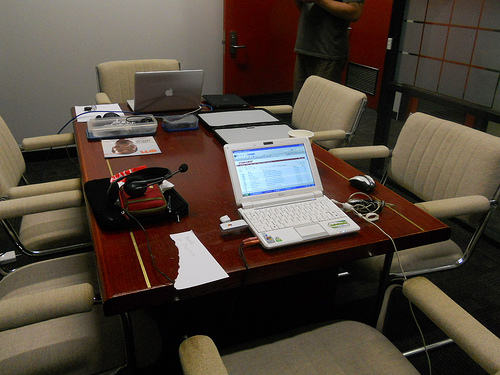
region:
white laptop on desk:
[217, 140, 364, 252]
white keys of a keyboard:
[241, 196, 349, 231]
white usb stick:
[220, 216, 252, 231]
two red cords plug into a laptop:
[241, 234, 266, 245]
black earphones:
[101, 163, 191, 198]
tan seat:
[258, 74, 367, 143]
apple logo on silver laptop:
[159, 84, 179, 101]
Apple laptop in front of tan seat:
[91, 56, 204, 118]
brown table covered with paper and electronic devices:
[73, 71, 450, 309]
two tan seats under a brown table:
[254, 74, 499, 219]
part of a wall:
[147, 2, 179, 27]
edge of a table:
[219, 247, 261, 283]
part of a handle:
[44, 285, 98, 331]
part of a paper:
[174, 243, 199, 280]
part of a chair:
[321, 328, 350, 353]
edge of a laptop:
[254, 224, 306, 256]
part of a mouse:
[353, 172, 382, 198]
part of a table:
[246, 278, 331, 319]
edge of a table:
[109, 295, 130, 309]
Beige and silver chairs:
[6, 50, 496, 368]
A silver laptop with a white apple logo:
[121, 57, 213, 117]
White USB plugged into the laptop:
[215, 209, 251, 236]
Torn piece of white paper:
[149, 227, 239, 311]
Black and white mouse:
[341, 165, 391, 212]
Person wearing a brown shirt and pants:
[291, 5, 380, 125]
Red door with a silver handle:
[220, 5, 317, 115]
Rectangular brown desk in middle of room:
[56, 95, 451, 325]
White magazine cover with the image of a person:
[96, 127, 176, 172]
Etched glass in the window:
[401, 8, 497, 129]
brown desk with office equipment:
[48, 63, 378, 360]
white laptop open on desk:
[213, 115, 362, 251]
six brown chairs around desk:
[16, 48, 437, 360]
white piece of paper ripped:
[162, 233, 249, 325]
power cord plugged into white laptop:
[330, 187, 452, 373]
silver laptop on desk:
[116, 48, 236, 120]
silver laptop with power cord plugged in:
[24, 69, 221, 116]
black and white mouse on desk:
[328, 156, 407, 226]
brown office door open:
[192, 1, 499, 136]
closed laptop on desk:
[201, 96, 296, 160]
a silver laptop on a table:
[127, 63, 210, 117]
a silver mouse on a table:
[348, 168, 373, 193]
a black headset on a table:
[102, 150, 197, 202]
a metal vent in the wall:
[335, 57, 380, 97]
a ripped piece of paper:
[161, 225, 226, 285]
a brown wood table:
[70, 95, 448, 312]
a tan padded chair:
[258, 74, 368, 144]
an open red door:
[218, 2, 311, 99]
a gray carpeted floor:
[0, 104, 498, 371]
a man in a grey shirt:
[288, 2, 359, 95]